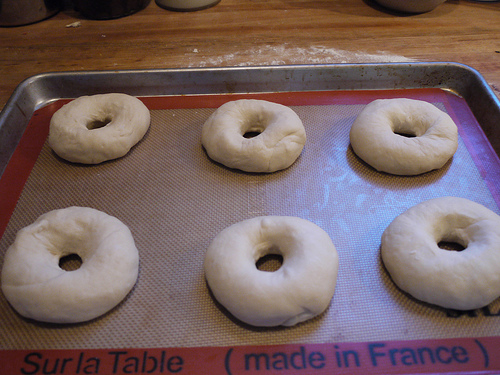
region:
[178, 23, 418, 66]
the flour on the table top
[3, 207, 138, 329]
the fresh dough on the cookie sheet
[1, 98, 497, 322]
the doughnuts on the cookie sheet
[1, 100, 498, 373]
the mat under the doughnuts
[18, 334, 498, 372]
the black writing on the mat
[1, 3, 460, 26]
the base of cannisters on the table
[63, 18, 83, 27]
the crumb on the counter top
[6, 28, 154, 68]
the black marks on the counter top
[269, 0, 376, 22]
the shadow of the cannister on the counter top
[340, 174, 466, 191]
the round shadow of the doughnuts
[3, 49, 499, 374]
uncooked dough on the tray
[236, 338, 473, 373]
black writing on a red background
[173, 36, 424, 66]
white powder on the tabletop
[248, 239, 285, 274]
hole in the middle of the dough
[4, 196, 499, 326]
row of three donuts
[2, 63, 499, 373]
food on a tray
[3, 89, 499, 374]
mat on the tray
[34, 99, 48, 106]
light glare on the silver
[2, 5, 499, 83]
light brown wood on the countertop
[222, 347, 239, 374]
black parenthese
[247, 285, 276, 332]
part of a doughnut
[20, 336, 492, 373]
some writing on the table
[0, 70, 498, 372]
a tray filled with donuts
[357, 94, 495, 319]
the donuts sitting to the right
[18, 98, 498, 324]
raw donuts sitting on the table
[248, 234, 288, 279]
the center of the bottom donut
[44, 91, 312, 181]
two more donuts on the table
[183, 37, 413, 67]
flour sitting on the table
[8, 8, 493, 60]
the table the donuts are sitting on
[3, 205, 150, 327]
a large uncooked donut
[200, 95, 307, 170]
the donut in the center on top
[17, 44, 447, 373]
pan with pastries in it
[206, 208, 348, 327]
pastry on the pan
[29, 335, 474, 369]
lettering on the image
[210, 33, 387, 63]
flour on the table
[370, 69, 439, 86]
browned spot on pan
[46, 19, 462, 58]
wooden table pan is resting on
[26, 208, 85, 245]
indention in the dough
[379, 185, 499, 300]
large full and round pastry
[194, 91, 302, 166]
smaller less full pastry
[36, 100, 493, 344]
white covering over pan